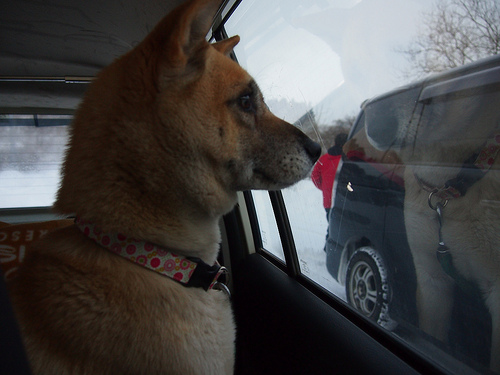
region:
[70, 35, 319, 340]
the dog is brown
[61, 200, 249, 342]
the collar is colorful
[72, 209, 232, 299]
female dog's collar with green, pink, and orange spots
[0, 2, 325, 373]
browin female dog with black accents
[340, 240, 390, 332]
snow covered week to a minivan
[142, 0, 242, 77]
female dog's perky ears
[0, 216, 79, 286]
orange sign with upside down white lettering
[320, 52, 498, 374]
dark navy blue minivan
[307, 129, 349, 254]
man standing behind the van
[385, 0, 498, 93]
large tree with bare branches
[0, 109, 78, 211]
rear windshield with antenna and defroster lines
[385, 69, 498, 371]
reflection of the dog in the window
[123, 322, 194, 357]
PAtch of golden brown hair on animal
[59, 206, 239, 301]
Colorful colar on a dog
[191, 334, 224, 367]
PAtch of golden brown hair on animal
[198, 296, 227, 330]
PAtch of golden brown hair on animal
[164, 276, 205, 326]
PAtch of golden brown hair on animal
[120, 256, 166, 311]
PAtch of golden brown hair on animal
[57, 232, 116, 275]
PAtch of golden brown hair on animal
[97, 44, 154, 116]
PAtch of golden brown hair on animal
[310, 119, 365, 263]
PErson wearing red jacket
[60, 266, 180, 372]
PAtch of golden brown hair on animal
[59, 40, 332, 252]
a dog in a car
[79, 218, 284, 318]
a dog wearing a collar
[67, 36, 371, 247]
the head of a dog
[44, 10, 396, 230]
a dog looking out the window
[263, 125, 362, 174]
nose of a dog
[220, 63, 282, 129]
eye of a dog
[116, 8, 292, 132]
ears of a dog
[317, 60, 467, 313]
the back wheel on a van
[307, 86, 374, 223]
a man in a red jacket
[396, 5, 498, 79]
a tree with no leaves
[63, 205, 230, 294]
A PINK AND WHITE DOG COLLAR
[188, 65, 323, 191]
A DOG WITH BROWN EYES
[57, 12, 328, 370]
A BLONDE COLORED DOG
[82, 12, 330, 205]
PROFILE SHOT OF A DOG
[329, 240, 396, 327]
VAN TIRE WITH SNOW ON IT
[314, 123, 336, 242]
A PERSON IN RED JACKET OUTSIDE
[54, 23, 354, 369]
A DOG INSIDE A VEHICLE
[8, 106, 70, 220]
THE REAR WINDOW OF VEHILE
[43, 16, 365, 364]
A WELL BEHAVED DOG WATCHES OTHERS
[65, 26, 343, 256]
A TAN COLORED DOG IN CAR